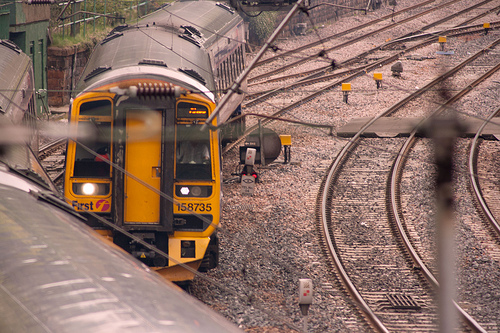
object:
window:
[217, 44, 245, 98]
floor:
[311, 105, 346, 119]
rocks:
[265, 250, 307, 277]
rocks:
[458, 252, 493, 287]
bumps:
[278, 135, 292, 164]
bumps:
[372, 72, 383, 90]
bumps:
[482, 22, 490, 35]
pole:
[298, 278, 312, 316]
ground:
[250, 190, 300, 249]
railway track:
[313, 130, 495, 330]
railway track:
[241, 0, 500, 131]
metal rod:
[318, 188, 332, 245]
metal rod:
[355, 48, 375, 56]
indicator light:
[251, 174, 256, 178]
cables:
[217, 40, 386, 108]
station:
[32, 71, 242, 331]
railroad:
[315, 0, 500, 333]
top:
[0, 165, 250, 333]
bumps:
[341, 83, 351, 103]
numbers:
[177, 202, 212, 211]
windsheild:
[175, 124, 212, 180]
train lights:
[80, 183, 100, 196]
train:
[58, 0, 249, 281]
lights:
[81, 182, 97, 195]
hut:
[0, 0, 52, 128]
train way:
[47, 0, 499, 328]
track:
[313, 188, 442, 300]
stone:
[348, 195, 370, 221]